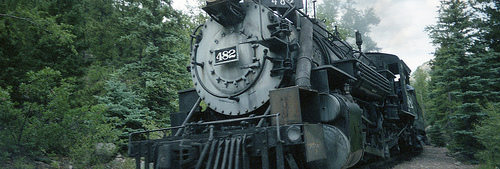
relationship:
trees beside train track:
[472, 101, 499, 168] [364, 147, 424, 167]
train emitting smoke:
[161, 24, 454, 160] [307, 1, 439, 65]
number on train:
[227, 49, 235, 58] [126, 0, 426, 168]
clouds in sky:
[385, 2, 443, 63] [168, 0, 498, 77]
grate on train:
[180, 133, 280, 167] [126, 0, 426, 168]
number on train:
[212, 48, 238, 66] [126, 0, 426, 168]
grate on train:
[193, 133, 250, 168] [126, 0, 426, 168]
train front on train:
[127, 0, 349, 167] [126, 0, 426, 168]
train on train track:
[126, 0, 426, 168] [387, 147, 424, 166]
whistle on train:
[344, 24, 368, 50] [164, 14, 439, 165]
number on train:
[227, 49, 235, 58] [176, 5, 447, 163]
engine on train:
[318, 90, 365, 167] [126, 0, 426, 168]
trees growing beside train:
[408, 2, 499, 164] [126, 0, 426, 168]